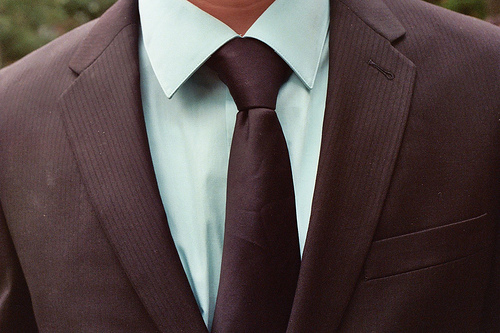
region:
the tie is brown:
[190, 30, 290, 330]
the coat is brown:
[4, 0, 471, 330]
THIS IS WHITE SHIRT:
[129, 0, 334, 310]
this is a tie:
[171, 41, 318, 324]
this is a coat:
[4, 18, 498, 327]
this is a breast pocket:
[346, 188, 492, 307]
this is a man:
[0, 4, 490, 322]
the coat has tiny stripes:
[4, 0, 168, 326]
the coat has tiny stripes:
[339, 63, 400, 189]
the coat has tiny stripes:
[292, 4, 488, 291]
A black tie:
[203, 30, 302, 331]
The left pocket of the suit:
[352, 205, 497, 285]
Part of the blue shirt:
[170, 141, 186, 203]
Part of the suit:
[35, 165, 91, 266]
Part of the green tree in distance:
[11, 7, 51, 34]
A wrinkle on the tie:
[233, 228, 268, 258]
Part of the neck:
[222, 6, 248, 18]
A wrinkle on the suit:
[2, 260, 19, 311]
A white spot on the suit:
[39, 157, 66, 196]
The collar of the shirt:
[136, 0, 343, 102]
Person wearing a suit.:
[0, 0, 495, 330]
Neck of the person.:
[181, 0, 291, 35]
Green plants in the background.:
[0, 0, 110, 77]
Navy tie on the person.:
[198, 33, 304, 329]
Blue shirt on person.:
[132, 0, 339, 331]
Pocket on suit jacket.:
[355, 199, 499, 283]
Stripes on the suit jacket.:
[7, 0, 494, 329]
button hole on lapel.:
[363, 53, 395, 83]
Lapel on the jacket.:
[282, 0, 414, 331]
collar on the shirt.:
[131, 0, 330, 110]